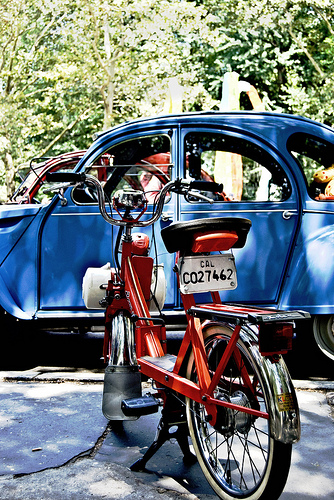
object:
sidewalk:
[0, 357, 334, 498]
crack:
[0, 419, 111, 480]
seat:
[160, 215, 252, 258]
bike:
[26, 155, 314, 498]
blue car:
[0, 109, 334, 368]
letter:
[206, 258, 211, 265]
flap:
[101, 362, 150, 423]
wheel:
[183, 329, 296, 498]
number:
[212, 269, 219, 281]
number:
[219, 268, 228, 281]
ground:
[0, 364, 334, 499]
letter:
[181, 269, 190, 284]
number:
[204, 268, 210, 280]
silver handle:
[159, 209, 174, 226]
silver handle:
[83, 170, 123, 228]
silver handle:
[282, 207, 299, 219]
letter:
[199, 258, 207, 271]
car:
[5, 152, 228, 210]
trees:
[0, 0, 58, 219]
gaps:
[130, 461, 148, 472]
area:
[0, 106, 334, 496]